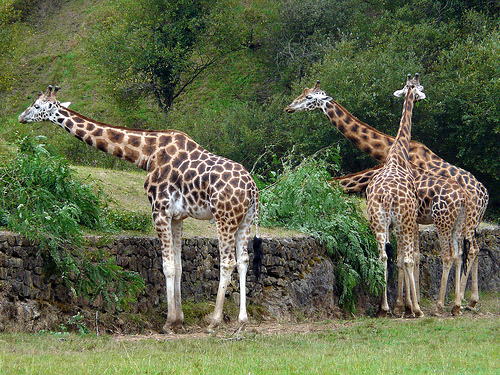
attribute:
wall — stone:
[18, 232, 331, 326]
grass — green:
[24, 322, 474, 374]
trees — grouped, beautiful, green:
[52, 20, 483, 151]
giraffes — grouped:
[25, 77, 490, 334]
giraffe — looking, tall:
[19, 84, 277, 335]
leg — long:
[151, 231, 177, 329]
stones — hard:
[13, 256, 49, 300]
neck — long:
[328, 101, 391, 154]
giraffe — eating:
[278, 83, 489, 223]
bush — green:
[258, 146, 364, 269]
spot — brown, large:
[153, 147, 177, 181]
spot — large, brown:
[333, 110, 342, 125]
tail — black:
[251, 202, 267, 253]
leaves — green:
[292, 189, 317, 212]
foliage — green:
[19, 168, 133, 309]